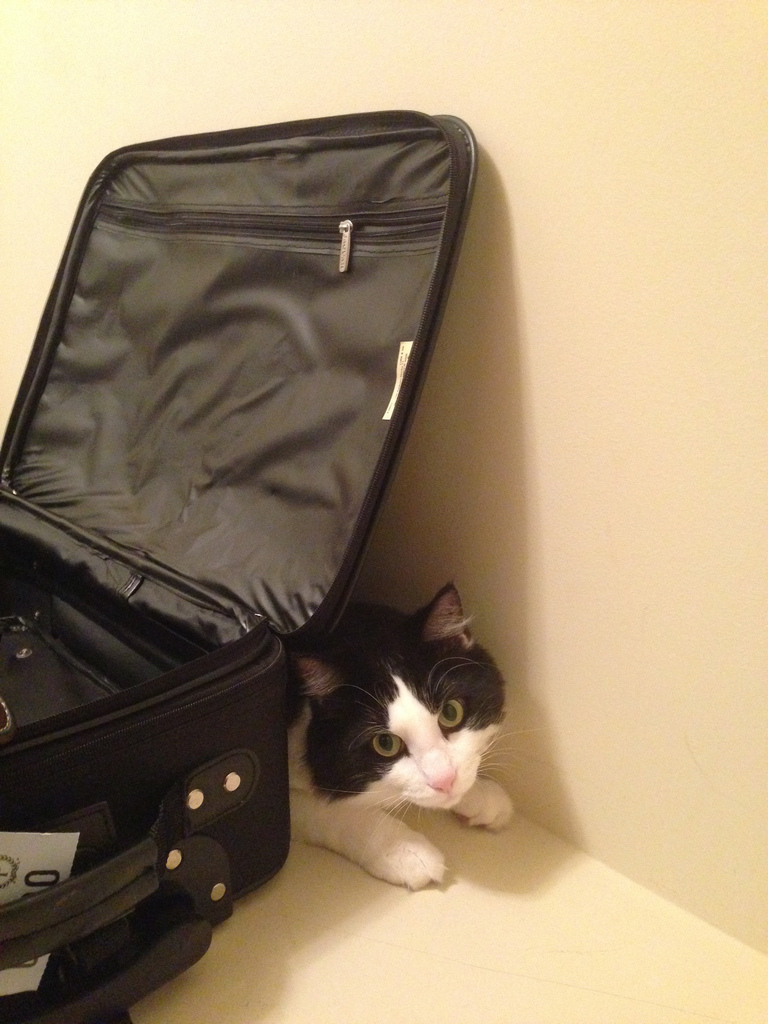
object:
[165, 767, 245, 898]
rivets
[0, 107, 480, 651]
leather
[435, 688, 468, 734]
eye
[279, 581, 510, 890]
animal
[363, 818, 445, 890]
paw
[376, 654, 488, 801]
face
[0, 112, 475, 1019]
suitcase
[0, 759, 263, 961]
handles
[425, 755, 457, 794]
nose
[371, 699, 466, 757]
eyes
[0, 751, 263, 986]
handle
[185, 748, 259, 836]
trim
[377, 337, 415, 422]
tag